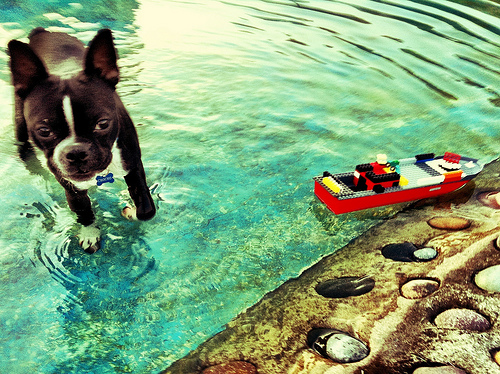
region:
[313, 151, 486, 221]
a red logo boat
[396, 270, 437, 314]
rocks in the sand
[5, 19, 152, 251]
a dog in water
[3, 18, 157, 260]
a black and white dog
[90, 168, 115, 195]
a blue dog tag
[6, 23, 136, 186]
a dogs head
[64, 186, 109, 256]
a dogs right foot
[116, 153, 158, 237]
a dogs left food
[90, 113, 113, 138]
left eye of a dog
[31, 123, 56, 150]
right eye of a dog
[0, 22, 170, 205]
black and white dog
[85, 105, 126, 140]
eye of the dog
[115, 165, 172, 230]
leg of the dog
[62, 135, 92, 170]
nose of the dog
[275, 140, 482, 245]
toy boat in the water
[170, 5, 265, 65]
light in the water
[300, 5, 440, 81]
ripples in the water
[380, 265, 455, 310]
rock on the land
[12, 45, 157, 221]
dog looking towards the camera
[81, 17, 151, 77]
ear of the dog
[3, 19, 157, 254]
Black and white puppy.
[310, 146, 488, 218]
Colorful lego boat.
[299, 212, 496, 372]
Multiple rocks in cement.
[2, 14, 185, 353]
Dog standing in water.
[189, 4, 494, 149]
Ripples in clear water.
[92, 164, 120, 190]
Blue dog name tag.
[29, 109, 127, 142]
Pair of dog eyes.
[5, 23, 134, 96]
Pair of dog ears.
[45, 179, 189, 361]
Reflection of dog in water.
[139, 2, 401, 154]
Reflection of sun on water.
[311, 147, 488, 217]
a lego boat on water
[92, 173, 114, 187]
a dog's bone shaped name tag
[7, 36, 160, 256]
a dog in the water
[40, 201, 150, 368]
a dog's reflection in the water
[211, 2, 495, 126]
ripples in the water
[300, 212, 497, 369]
stones lodged in a rock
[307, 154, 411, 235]
a reflection of the boat in the water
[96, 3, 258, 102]
a light's reflection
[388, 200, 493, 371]
small stones in a rock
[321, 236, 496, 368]
rocks embedded in concrete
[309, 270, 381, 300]
oval shaped black rock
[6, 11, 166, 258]
black dog in water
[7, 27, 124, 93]
two black dog ears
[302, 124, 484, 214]
one red Lego boat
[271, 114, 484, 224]
red toy boat in water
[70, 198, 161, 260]
two black and white dog legs in water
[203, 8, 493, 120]
ripples on body of water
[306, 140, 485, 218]
tip of boat on concrete bank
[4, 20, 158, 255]
dog walking in shallow water